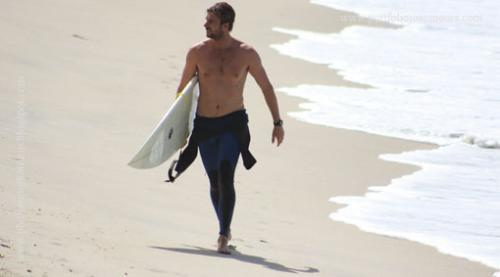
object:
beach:
[2, 0, 497, 277]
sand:
[0, 0, 495, 277]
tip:
[122, 158, 155, 170]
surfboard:
[124, 68, 198, 175]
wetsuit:
[190, 107, 256, 236]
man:
[172, 3, 285, 255]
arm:
[178, 46, 196, 102]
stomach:
[198, 93, 243, 119]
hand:
[270, 123, 286, 147]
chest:
[196, 44, 245, 83]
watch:
[270, 119, 282, 129]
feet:
[217, 236, 230, 254]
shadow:
[145, 242, 319, 275]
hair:
[202, 46, 240, 75]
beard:
[204, 28, 224, 40]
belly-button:
[212, 106, 222, 109]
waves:
[443, 126, 500, 151]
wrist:
[270, 118, 285, 124]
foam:
[449, 127, 500, 151]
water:
[268, 0, 500, 275]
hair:
[206, 0, 234, 29]